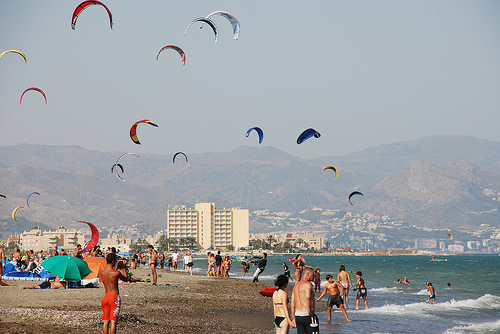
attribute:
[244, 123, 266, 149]
kite — blue, in air, different color, in the air, in the sky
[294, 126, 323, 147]
kite — blue, in air, different color, in the air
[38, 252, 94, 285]
umbrella — green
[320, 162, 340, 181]
kite — different color, in the air, yellow, in the sky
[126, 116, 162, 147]
kite — different color, in the air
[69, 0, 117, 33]
kite — different color, in the air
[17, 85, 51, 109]
kite — red, in the air